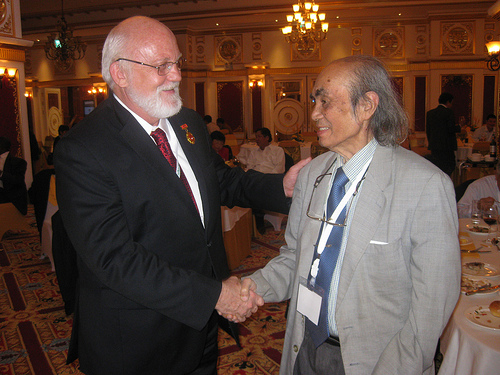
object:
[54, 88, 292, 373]
suit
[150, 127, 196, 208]
tie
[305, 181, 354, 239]
glasses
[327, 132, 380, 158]
neck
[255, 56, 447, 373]
man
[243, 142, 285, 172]
shirt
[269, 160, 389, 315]
strap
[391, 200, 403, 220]
ground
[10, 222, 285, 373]
rug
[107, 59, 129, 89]
ear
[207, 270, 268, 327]
shaking hands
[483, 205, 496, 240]
wine glass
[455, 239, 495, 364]
table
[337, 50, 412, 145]
hair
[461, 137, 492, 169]
dishes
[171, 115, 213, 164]
badge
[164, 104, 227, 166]
lapel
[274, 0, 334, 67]
chandelier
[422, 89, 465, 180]
person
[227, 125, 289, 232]
person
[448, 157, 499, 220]
person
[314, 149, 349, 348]
tag holder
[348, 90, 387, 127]
ear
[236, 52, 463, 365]
person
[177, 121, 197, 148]
medal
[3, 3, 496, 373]
room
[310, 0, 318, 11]
light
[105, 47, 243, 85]
glasses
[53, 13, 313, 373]
person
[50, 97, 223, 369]
jacket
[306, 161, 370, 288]
lanyard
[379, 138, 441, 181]
shoulder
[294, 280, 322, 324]
tag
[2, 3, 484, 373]
banquet hall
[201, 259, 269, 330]
hands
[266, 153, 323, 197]
hand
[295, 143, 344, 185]
shoulder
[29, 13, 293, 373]
man